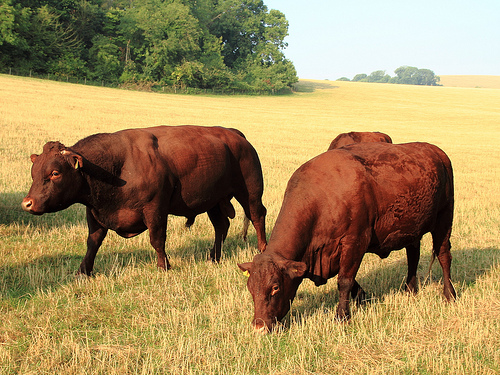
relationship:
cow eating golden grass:
[216, 131, 496, 345] [2, 79, 499, 374]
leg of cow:
[403, 239, 420, 292] [216, 131, 496, 345]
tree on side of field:
[240, 40, 300, 95] [4, 68, 495, 373]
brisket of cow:
[95, 203, 145, 241] [220, 121, 484, 338]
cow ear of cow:
[67, 153, 82, 170] [23, 96, 262, 296]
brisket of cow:
[304, 244, 341, 276] [216, 131, 496, 345]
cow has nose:
[23, 96, 262, 296] [17, 193, 40, 213]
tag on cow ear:
[74, 158, 78, 170] [67, 153, 82, 170]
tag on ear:
[241, 267, 250, 277] [269, 253, 321, 288]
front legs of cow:
[329, 252, 376, 323] [216, 131, 496, 345]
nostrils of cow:
[17, 198, 32, 209] [24, 88, 290, 296]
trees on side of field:
[1, 1, 302, 101] [4, 68, 495, 373]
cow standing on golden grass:
[23, 96, 262, 296] [2, 79, 499, 374]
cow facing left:
[23, 96, 262, 296] [5, 178, 144, 310]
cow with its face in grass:
[216, 131, 496, 345] [104, 262, 242, 348]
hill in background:
[432, 70, 499, 90] [1, 68, 496, 180]